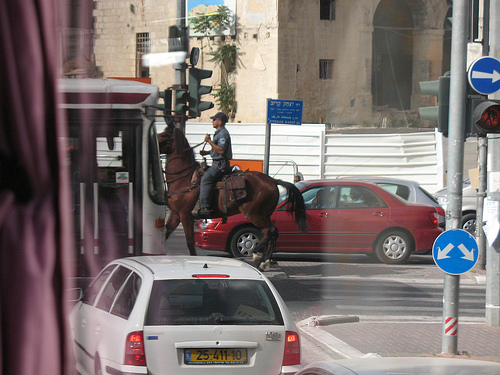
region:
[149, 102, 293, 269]
man on horseback in traffic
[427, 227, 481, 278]
round blue sign with arrows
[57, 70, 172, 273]
front of a bus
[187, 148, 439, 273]
red car behind man on horse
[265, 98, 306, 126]
blue metal traffic sing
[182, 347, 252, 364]
yellow license plate on car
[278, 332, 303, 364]
brake light on white car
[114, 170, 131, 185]
sticker on window of bus door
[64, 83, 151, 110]
red stripe at the top of the bus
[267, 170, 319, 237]
black tail of brown horse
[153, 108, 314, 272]
a mounted police officer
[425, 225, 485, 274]
a round blue sign with white arrows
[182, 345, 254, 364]
a yellow license plate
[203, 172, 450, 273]
a red car on the road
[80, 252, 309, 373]
a white station wagon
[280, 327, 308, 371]
a red tail light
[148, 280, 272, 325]
the back window of a car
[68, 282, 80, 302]
a sideview mirror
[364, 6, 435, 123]
an arched opening in a building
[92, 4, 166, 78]
a concrete block wall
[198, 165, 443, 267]
red car in street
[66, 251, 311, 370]
white car in street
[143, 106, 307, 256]
officer on brown horse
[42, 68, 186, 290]
white bus in intersection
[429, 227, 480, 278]
round blue traffic sign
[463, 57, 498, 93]
round blue traffic sign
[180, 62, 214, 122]
electric traffic control signal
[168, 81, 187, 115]
electric traffic control signal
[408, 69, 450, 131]
electric traffic control signal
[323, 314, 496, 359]
a brick paved sidewalk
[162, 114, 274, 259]
brown horse in the middle of the road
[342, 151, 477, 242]
the sign is blue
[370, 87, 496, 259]
the sign is blue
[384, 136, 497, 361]
the sign is blue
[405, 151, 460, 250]
the sign is blue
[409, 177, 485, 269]
the sign is blue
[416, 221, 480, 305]
the sign is blue